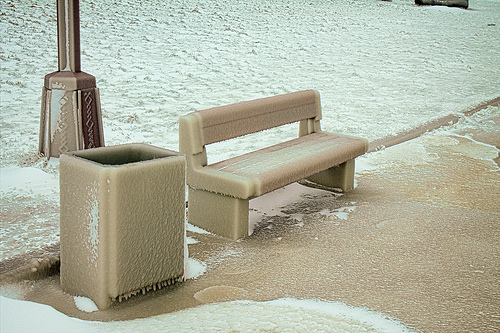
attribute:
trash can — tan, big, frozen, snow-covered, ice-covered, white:
[59, 143, 186, 306]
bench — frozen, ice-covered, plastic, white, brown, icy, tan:
[178, 89, 369, 240]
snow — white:
[0, 294, 104, 332]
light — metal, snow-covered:
[38, 1, 105, 160]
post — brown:
[56, 1, 81, 70]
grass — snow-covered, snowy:
[0, 0, 500, 261]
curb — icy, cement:
[0, 95, 499, 284]